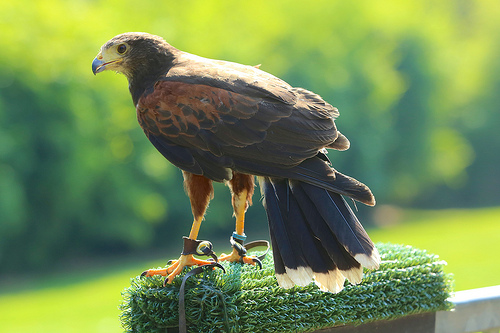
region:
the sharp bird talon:
[144, 212, 237, 304]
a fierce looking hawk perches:
[78, 23, 414, 294]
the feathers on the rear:
[258, 175, 384, 293]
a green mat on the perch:
[106, 248, 496, 325]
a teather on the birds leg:
[164, 218, 296, 252]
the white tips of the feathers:
[276, 263, 388, 303]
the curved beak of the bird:
[85, 57, 104, 75]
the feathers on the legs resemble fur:
[179, 171, 230, 226]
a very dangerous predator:
[73, 35, 385, 281]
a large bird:
[87, 30, 378, 292]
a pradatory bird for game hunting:
[86, 30, 381, 295]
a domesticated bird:
[90, 30, 375, 295]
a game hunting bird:
[87, 30, 377, 295]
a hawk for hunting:
[90, 30, 385, 295]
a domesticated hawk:
[90, 30, 375, 295]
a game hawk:
[86, 30, 377, 290]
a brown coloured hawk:
[90, 30, 380, 290]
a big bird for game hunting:
[90, 30, 380, 291]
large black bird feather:
[274, 170, 318, 292]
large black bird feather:
[293, 177, 343, 290]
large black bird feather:
[303, 175, 395, 271]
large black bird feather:
[293, 148, 374, 203]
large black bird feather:
[146, 120, 233, 176]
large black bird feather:
[231, 158, 282, 176]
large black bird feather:
[258, 145, 303, 167]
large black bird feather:
[263, 125, 318, 155]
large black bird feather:
[286, 110, 348, 151]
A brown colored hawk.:
[91, 28, 378, 293]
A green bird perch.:
[119, 238, 456, 330]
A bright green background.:
[1, 0, 499, 332]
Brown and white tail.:
[261, 150, 379, 295]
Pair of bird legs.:
[139, 188, 264, 285]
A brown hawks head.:
[89, 28, 178, 85]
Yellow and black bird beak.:
[91, 49, 116, 76]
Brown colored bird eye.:
[116, 40, 126, 55]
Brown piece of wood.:
[310, 305, 436, 330]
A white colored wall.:
[436, 283, 498, 331]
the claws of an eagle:
[139, 247, 225, 299]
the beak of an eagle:
[67, 39, 107, 89]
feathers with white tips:
[285, 269, 370, 289]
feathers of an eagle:
[261, 181, 401, 275]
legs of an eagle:
[153, 176, 218, 323]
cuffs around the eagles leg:
[179, 234, 223, 258]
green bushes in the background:
[311, 4, 481, 157]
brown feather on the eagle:
[139, 78, 237, 123]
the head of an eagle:
[63, 23, 190, 115]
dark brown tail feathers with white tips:
[251, 165, 386, 300]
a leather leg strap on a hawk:
[168, 227, 232, 331]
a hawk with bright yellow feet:
[83, 31, 391, 295]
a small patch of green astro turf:
[123, 227, 462, 329]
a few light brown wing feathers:
[141, 76, 245, 131]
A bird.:
[83, 23, 400, 295]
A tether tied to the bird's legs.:
[160, 220, 274, 326]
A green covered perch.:
[122, 231, 450, 331]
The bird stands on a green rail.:
[73, 28, 463, 323]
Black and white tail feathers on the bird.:
[261, 161, 389, 307]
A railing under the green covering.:
[416, 288, 498, 328]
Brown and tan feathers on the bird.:
[124, 68, 310, 153]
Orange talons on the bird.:
[146, 240, 269, 288]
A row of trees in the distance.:
[18, 10, 497, 251]